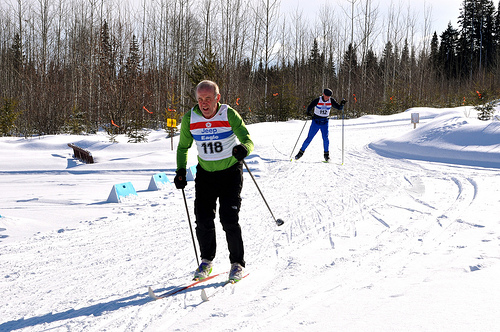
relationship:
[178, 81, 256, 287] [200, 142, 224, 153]
skiier has number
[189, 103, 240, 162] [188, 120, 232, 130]
vest has stripe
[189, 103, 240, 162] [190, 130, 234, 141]
vest has stripe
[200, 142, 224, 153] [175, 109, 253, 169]
number on front of coat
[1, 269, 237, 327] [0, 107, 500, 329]
shadow on top of ground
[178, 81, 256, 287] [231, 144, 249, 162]
skiier has hand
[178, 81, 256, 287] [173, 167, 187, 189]
skiier has hand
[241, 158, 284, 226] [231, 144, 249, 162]
skiing pole inside of hand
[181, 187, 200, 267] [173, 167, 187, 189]
skiing pole inside of hand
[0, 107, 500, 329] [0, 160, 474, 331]
ground covered in tracks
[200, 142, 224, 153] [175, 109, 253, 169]
number on top of sweater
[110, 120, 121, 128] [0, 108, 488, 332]
flag marks trail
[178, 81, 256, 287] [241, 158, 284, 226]
skiier has skiing pole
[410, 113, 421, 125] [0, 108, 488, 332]
sign on side of trail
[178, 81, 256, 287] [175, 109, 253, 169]
skiier wearing sweater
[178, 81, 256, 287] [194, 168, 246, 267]
skiier wearing pants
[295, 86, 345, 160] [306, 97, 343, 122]
skiier wearing sweater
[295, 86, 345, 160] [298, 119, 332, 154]
skiier wearing pants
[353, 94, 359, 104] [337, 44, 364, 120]
flag tied to tree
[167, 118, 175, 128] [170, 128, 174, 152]
sign on top of pole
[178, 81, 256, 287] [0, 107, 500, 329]
skiier on top of snow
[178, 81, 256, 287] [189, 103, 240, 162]
skiier wearing vest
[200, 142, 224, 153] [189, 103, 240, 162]
number on top of vest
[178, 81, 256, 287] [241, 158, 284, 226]
skiier holding skiing pole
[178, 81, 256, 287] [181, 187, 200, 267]
skiier holding skiing pole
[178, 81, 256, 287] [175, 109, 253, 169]
skiier wears sweater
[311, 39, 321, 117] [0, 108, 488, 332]
tree behind trail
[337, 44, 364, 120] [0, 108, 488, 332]
tree behind trail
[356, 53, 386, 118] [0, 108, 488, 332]
tree behind trail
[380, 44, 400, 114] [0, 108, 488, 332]
tree behind trail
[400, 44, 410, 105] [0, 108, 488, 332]
tree behind trail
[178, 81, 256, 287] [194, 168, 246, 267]
skiier wears pants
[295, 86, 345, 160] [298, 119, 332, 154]
skiier wears pants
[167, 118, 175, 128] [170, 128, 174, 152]
sign on pole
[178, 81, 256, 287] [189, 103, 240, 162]
skiier wears vest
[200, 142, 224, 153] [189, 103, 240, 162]
number on vest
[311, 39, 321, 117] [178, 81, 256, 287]
tree behind skiier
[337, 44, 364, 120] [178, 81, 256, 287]
tree behind skiier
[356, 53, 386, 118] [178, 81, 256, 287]
tree behind skiier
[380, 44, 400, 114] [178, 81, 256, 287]
tree behind skiier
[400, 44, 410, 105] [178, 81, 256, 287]
tree behind skiier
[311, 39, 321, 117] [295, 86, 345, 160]
tree behind skiier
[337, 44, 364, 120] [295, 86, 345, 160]
tree behind skiier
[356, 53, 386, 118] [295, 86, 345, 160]
tree behind skiier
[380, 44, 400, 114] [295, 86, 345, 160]
tree behind skiier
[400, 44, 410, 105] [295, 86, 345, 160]
tree behind skiier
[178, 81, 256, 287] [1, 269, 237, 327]
skiier has shadow